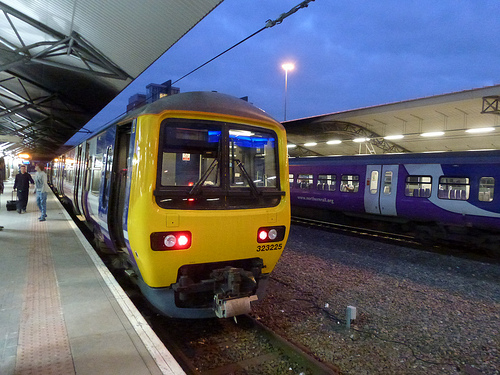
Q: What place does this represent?
A: It represents the train station.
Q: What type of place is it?
A: It is a train station.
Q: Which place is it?
A: It is a train station.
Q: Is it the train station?
A: Yes, it is the train station.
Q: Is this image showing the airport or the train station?
A: It is showing the train station.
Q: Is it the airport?
A: No, it is the train station.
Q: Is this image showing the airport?
A: No, the picture is showing the train station.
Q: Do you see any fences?
A: No, there are no fences.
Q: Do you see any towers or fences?
A: No, there are no fences or towers.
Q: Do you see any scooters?
A: No, there are no scooters.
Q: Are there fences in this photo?
A: No, there are no fences.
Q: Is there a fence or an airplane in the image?
A: No, there are no fences or airplanes.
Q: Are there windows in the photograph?
A: Yes, there is a window.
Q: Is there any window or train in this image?
A: Yes, there is a window.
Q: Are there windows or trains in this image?
A: Yes, there is a window.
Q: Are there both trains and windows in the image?
A: Yes, there are both a window and a train.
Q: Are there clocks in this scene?
A: No, there are no clocks.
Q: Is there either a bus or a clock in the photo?
A: No, there are no clocks or buses.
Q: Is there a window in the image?
A: Yes, there is a window.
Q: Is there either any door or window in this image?
A: Yes, there is a window.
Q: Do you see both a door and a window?
A: Yes, there are both a window and a door.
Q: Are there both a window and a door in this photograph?
A: Yes, there are both a window and a door.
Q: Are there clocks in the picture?
A: No, there are no clocks.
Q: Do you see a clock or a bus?
A: No, there are no clocks or buses.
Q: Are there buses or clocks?
A: No, there are no clocks or buses.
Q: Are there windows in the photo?
A: Yes, there is a window.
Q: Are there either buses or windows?
A: Yes, there is a window.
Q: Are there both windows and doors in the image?
A: Yes, there are both a window and a door.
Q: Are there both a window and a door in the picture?
A: Yes, there are both a window and a door.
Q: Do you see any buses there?
A: No, there are no buses.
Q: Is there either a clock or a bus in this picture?
A: No, there are no buses or clocks.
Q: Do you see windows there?
A: Yes, there is a window.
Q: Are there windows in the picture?
A: Yes, there is a window.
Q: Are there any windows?
A: Yes, there is a window.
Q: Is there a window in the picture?
A: Yes, there is a window.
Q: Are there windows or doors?
A: Yes, there is a window.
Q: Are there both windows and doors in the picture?
A: Yes, there are both a window and doors.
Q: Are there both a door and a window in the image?
A: Yes, there are both a window and a door.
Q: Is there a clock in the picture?
A: No, there are no clocks.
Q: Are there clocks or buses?
A: No, there are no clocks or buses.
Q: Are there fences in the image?
A: No, there are no fences.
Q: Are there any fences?
A: No, there are no fences.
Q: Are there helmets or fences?
A: No, there are no fences or helmets.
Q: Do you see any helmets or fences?
A: No, there are no fences or helmets.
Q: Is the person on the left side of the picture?
A: Yes, the person is on the left of the image.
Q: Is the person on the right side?
A: No, the person is on the left of the image.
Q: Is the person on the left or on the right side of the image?
A: The person is on the left of the image.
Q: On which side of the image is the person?
A: The person is on the left of the image.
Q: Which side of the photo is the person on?
A: The person is on the left of the image.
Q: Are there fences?
A: No, there are no fences.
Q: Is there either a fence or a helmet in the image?
A: No, there are no fences or helmets.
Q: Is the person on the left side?
A: Yes, the person is on the left of the image.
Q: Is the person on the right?
A: No, the person is on the left of the image.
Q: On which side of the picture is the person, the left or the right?
A: The person is on the left of the image.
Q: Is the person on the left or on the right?
A: The person is on the left of the image.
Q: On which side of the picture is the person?
A: The person is on the left of the image.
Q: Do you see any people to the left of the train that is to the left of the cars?
A: Yes, there is a person to the left of the train.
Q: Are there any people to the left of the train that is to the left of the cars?
A: Yes, there is a person to the left of the train.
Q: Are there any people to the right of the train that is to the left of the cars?
A: No, the person is to the left of the train.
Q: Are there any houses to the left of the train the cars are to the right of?
A: No, there is a person to the left of the train.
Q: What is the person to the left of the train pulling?
A: The person is pulling luggage.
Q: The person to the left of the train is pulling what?
A: The person is pulling luggage.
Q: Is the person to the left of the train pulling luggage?
A: Yes, the person is pulling luggage.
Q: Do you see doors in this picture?
A: Yes, there is a door.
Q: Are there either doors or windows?
A: Yes, there is a door.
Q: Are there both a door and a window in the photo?
A: Yes, there are both a door and a window.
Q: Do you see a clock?
A: No, there are no clocks.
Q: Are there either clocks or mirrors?
A: No, there are no clocks or mirrors.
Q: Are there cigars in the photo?
A: No, there are no cigars.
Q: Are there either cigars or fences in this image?
A: No, there are no cigars or fences.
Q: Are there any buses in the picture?
A: No, there are no buses.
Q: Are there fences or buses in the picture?
A: No, there are no buses or fences.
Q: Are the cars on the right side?
A: Yes, the cars are on the right of the image.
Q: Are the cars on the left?
A: No, the cars are on the right of the image.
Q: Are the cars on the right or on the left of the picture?
A: The cars are on the right of the image.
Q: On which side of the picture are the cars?
A: The cars are on the right of the image.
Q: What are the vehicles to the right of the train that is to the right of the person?
A: The vehicles are cars.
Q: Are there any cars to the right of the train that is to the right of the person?
A: Yes, there are cars to the right of the train.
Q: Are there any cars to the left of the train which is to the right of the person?
A: No, the cars are to the right of the train.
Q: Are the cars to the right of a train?
A: Yes, the cars are to the right of a train.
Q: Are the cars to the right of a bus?
A: No, the cars are to the right of a train.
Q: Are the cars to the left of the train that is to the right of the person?
A: No, the cars are to the right of the train.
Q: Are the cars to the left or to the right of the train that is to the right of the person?
A: The cars are to the right of the train.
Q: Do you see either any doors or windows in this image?
A: Yes, there is a window.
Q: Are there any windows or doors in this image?
A: Yes, there is a window.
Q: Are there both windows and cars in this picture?
A: Yes, there are both a window and a car.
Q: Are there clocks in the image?
A: No, there are no clocks.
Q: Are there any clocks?
A: No, there are no clocks.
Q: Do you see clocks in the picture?
A: No, there are no clocks.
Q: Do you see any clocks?
A: No, there are no clocks.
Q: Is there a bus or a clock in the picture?
A: No, there are no clocks or buses.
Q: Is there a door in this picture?
A: Yes, there is a door.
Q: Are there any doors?
A: Yes, there is a door.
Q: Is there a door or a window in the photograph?
A: Yes, there is a door.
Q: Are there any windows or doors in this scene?
A: Yes, there is a door.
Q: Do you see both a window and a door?
A: Yes, there are both a door and a window.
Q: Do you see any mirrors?
A: No, there are no mirrors.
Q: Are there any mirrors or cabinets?
A: No, there are no mirrors or cabinets.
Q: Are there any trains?
A: Yes, there is a train.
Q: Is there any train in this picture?
A: Yes, there is a train.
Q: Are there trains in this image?
A: Yes, there is a train.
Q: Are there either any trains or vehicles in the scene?
A: Yes, there is a train.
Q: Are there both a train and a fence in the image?
A: No, there is a train but no fences.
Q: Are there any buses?
A: No, there are no buses.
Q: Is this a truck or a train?
A: This is a train.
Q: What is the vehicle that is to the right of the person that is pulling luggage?
A: The vehicle is a train.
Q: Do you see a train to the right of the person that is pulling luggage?
A: Yes, there is a train to the right of the person.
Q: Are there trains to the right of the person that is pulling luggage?
A: Yes, there is a train to the right of the person.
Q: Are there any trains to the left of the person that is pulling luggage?
A: No, the train is to the right of the person.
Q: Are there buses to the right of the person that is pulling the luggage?
A: No, there is a train to the right of the person.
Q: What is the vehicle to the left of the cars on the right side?
A: The vehicle is a train.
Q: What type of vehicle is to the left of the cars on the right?
A: The vehicle is a train.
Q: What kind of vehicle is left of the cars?
A: The vehicle is a train.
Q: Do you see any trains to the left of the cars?
A: Yes, there is a train to the left of the cars.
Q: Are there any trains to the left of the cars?
A: Yes, there is a train to the left of the cars.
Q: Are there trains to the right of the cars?
A: No, the train is to the left of the cars.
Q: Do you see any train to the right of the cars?
A: No, the train is to the left of the cars.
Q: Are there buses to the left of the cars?
A: No, there is a train to the left of the cars.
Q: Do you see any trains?
A: Yes, there is a train.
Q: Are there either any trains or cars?
A: Yes, there is a train.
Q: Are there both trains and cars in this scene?
A: Yes, there are both a train and a car.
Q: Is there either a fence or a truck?
A: No, there are no fences or trucks.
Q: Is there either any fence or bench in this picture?
A: No, there are no fences or benches.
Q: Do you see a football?
A: No, there are no footballs.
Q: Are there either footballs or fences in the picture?
A: No, there are no footballs or fences.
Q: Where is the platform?
A: The platform is in the train station.